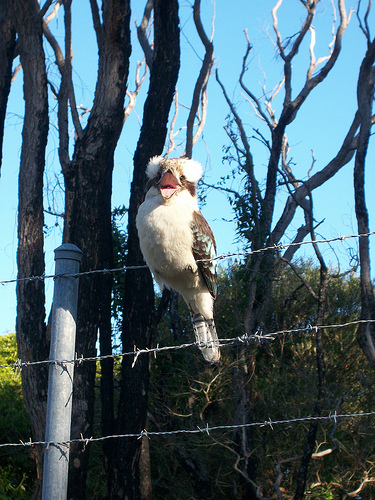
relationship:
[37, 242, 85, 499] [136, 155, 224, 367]
pole near bird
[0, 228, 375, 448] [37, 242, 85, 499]
fence next to pole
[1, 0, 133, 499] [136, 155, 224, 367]
tree behind bird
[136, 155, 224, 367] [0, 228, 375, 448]
bird on fence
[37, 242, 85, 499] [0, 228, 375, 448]
pole connects fence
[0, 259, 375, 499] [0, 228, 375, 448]
shrubbery behind fence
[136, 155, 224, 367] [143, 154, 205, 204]
bird has head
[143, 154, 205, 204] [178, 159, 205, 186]
head has feathers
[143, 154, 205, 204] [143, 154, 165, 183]
head has feathers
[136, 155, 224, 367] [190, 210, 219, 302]
bird has feathers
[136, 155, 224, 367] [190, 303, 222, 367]
bird has feathers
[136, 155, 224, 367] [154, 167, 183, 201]
bird has beak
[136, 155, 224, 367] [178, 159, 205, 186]
bird has feathers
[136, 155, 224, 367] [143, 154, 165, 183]
bird has feathers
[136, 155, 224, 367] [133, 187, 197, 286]
bird has feathers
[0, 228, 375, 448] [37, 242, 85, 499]
fence has pole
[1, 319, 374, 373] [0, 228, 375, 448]
barbed wire on fence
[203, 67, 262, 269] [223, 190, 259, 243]
tree has leaves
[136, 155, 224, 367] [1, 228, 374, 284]
bird on barbed wire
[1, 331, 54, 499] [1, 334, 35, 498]
tree has leaves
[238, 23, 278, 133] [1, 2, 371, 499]
branch near forest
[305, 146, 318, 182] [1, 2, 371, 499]
branch near forest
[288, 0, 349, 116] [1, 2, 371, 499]
branch near forest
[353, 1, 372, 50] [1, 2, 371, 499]
branch near forest